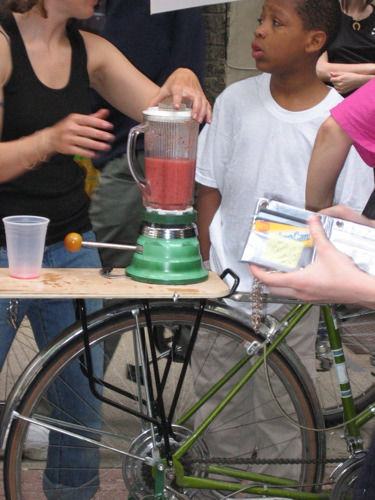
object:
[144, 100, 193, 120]
lid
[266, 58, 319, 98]
neck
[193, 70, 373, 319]
t-shirt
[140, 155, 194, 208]
smoothie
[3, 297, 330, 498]
tire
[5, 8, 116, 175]
woman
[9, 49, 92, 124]
tank top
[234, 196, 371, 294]
wallet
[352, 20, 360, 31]
horseshoe charm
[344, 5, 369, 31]
necklace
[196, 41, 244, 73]
ground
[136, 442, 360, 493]
chain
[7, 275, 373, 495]
bike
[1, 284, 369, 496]
bike frame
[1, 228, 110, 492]
blue jeans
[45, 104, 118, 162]
hand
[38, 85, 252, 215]
platform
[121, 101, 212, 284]
blender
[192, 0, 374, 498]
boy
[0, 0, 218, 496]
teacher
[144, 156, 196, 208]
liquid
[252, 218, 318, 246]
card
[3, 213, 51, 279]
cup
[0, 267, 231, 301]
platform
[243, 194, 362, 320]
person